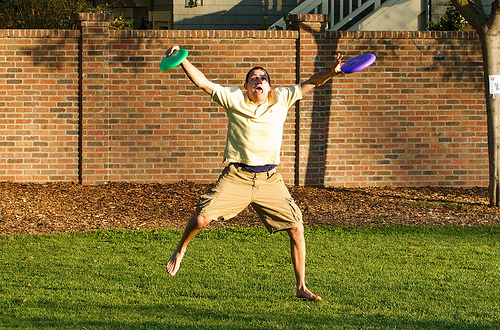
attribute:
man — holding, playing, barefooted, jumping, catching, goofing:
[138, 34, 396, 308]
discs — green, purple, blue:
[150, 38, 381, 83]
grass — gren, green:
[6, 228, 498, 328]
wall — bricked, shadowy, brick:
[6, 11, 499, 186]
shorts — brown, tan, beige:
[190, 154, 309, 240]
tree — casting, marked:
[442, 0, 500, 208]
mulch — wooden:
[1, 177, 498, 230]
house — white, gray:
[83, 0, 499, 32]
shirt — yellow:
[208, 83, 296, 165]